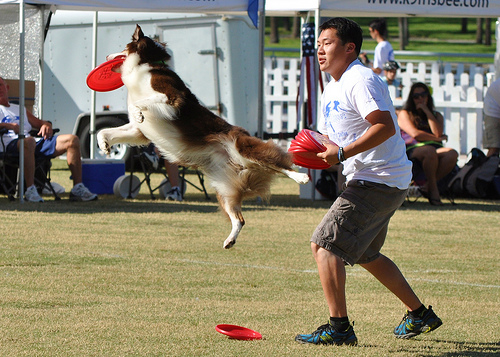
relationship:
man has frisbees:
[292, 16, 442, 346] [285, 125, 335, 170]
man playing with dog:
[292, 16, 442, 346] [97, 24, 310, 249]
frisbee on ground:
[213, 321, 265, 343] [3, 159, 499, 356]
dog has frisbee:
[97, 24, 310, 249] [83, 57, 131, 95]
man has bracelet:
[292, 16, 442, 346] [336, 145, 344, 166]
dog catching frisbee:
[97, 24, 310, 249] [83, 57, 131, 95]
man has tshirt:
[292, 16, 442, 346] [316, 60, 415, 191]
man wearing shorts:
[292, 16, 442, 346] [307, 179, 408, 268]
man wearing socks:
[292, 16, 442, 346] [327, 316, 353, 331]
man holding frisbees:
[292, 16, 442, 346] [285, 125, 335, 170]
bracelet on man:
[336, 145, 344, 166] [292, 16, 442, 346]